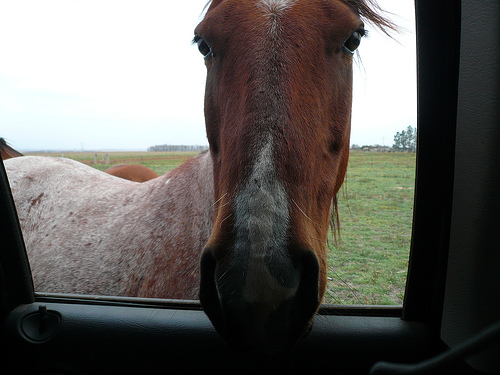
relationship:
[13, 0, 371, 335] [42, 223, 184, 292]
horse has stomach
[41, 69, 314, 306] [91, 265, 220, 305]
edge of window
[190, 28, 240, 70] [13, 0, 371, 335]
eye of horse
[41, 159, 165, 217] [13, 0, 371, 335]
back of horse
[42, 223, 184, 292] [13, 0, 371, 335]
stomach of horse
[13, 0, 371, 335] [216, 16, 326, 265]
horse has head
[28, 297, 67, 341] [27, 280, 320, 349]
lock on door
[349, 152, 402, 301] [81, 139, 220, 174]
field in field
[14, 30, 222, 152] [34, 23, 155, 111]
clouds in sky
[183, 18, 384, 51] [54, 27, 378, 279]
eyes on horse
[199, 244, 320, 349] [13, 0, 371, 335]
nose of horse